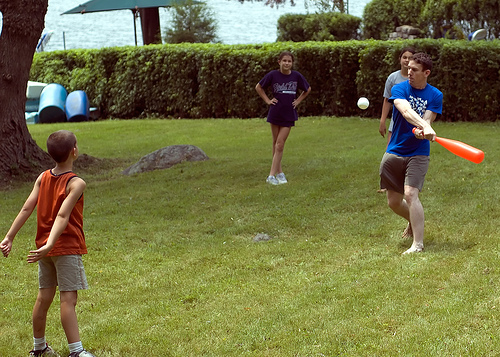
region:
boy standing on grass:
[2, 125, 99, 355]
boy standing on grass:
[375, 51, 446, 255]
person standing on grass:
[250, 44, 317, 188]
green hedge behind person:
[32, 37, 497, 124]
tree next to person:
[0, 1, 88, 179]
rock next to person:
[129, 139, 206, 176]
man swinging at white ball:
[355, 51, 483, 256]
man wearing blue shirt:
[379, 55, 487, 256]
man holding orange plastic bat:
[378, 52, 486, 253]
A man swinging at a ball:
[376, 52, 443, 255]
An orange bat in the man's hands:
[413, 125, 486, 163]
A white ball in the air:
[358, 95, 370, 108]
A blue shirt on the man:
[389, 81, 445, 158]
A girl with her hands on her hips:
[253, 51, 315, 182]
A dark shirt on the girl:
[255, 65, 311, 125]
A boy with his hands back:
[0, 132, 91, 355]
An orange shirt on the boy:
[30, 168, 90, 255]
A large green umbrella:
[58, 1, 178, 45]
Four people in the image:
[4, 31, 464, 356]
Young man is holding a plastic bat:
[354, 39, 491, 265]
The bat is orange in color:
[408, 115, 488, 175]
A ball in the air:
[348, 88, 376, 118]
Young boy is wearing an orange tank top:
[27, 157, 92, 264]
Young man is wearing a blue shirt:
[377, 74, 451, 163]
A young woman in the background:
[236, 40, 328, 190]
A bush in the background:
[29, 34, 499, 130]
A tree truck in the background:
[1, 0, 94, 178]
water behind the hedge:
[29, 0, 385, 55]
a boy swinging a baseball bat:
[350, 48, 488, 255]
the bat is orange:
[411, 126, 487, 169]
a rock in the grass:
[121, 133, 212, 176]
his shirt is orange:
[31, 170, 93, 262]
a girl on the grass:
[248, 39, 313, 187]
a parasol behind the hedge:
[64, 0, 183, 19]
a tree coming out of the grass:
[0, 0, 102, 190]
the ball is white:
[350, 94, 377, 109]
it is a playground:
[99, 183, 354, 333]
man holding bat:
[379, 53, 495, 261]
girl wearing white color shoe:
[262, 162, 304, 184]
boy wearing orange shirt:
[28, 161, 95, 262]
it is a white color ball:
[342, 79, 384, 122]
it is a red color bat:
[413, 115, 488, 180]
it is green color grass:
[157, 183, 345, 307]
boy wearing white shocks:
[27, 332, 87, 354]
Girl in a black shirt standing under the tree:
[255, 50, 312, 185]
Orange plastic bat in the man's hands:
[410, 126, 485, 163]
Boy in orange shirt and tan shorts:
[0, 130, 96, 355]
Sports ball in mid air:
[357, 96, 369, 108]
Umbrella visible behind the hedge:
[60, 0, 205, 45]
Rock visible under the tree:
[127, 143, 207, 174]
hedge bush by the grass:
[110, 45, 140, 115]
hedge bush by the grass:
[136, 43, 162, 111]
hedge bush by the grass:
[160, 38, 193, 114]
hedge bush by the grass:
[191, 45, 211, 113]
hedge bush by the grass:
[210, 37, 235, 117]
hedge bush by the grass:
[226, 43, 256, 113]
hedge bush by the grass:
[297, 40, 328, 111]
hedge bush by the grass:
[320, 38, 351, 113]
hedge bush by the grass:
[356, 40, 381, 117]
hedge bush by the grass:
[439, 37, 460, 120]